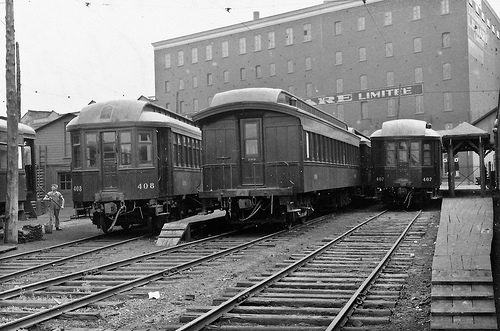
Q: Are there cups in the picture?
A: No, there are no cups.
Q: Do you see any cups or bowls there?
A: No, there are no cups or bowls.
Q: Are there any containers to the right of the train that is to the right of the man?
A: Yes, there is a container to the right of the train.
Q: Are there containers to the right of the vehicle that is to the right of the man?
A: Yes, there is a container to the right of the train.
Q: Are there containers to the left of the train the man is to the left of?
A: No, the container is to the right of the train.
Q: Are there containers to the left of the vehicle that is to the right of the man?
A: No, the container is to the right of the train.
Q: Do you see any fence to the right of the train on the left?
A: No, there is a container to the right of the train.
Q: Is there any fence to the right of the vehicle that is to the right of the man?
A: No, there is a container to the right of the train.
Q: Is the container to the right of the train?
A: Yes, the container is to the right of the train.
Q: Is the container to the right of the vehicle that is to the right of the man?
A: Yes, the container is to the right of the train.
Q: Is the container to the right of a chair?
A: No, the container is to the right of the train.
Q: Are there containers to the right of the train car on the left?
A: Yes, there is a container to the right of the train car.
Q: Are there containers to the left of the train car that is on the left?
A: No, the container is to the right of the train car.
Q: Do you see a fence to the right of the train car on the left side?
A: No, there is a container to the right of the train car.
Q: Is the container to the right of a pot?
A: No, the container is to the right of a train car.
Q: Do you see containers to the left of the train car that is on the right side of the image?
A: Yes, there is a container to the left of the train car.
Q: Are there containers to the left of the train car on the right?
A: Yes, there is a container to the left of the train car.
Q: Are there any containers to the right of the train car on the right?
A: No, the container is to the left of the train car.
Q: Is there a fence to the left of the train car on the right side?
A: No, there is a container to the left of the train car.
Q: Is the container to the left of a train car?
A: Yes, the container is to the left of a train car.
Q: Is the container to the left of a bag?
A: No, the container is to the left of a train car.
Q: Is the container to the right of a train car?
A: No, the container is to the left of a train car.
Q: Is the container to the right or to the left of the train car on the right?
A: The container is to the left of the train car.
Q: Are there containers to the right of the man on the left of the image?
A: Yes, there is a container to the right of the man.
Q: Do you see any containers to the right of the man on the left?
A: Yes, there is a container to the right of the man.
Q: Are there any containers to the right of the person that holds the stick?
A: Yes, there is a container to the right of the man.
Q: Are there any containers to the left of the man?
A: No, the container is to the right of the man.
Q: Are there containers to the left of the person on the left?
A: No, the container is to the right of the man.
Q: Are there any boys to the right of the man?
A: No, there is a container to the right of the man.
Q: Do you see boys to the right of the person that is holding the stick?
A: No, there is a container to the right of the man.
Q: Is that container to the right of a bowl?
A: No, the container is to the right of a man.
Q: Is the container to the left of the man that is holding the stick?
A: No, the container is to the right of the man.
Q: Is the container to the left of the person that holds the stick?
A: No, the container is to the right of the man.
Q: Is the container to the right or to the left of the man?
A: The container is to the right of the man.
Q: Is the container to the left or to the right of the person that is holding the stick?
A: The container is to the right of the man.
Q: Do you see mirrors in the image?
A: No, there are no mirrors.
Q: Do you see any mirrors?
A: No, there are no mirrors.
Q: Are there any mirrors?
A: No, there are no mirrors.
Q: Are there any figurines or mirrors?
A: No, there are no mirrors or figurines.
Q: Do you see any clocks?
A: No, there are no clocks.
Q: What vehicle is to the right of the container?
A: The vehicle is a train car.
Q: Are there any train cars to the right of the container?
A: Yes, there is a train car to the right of the container.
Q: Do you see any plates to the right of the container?
A: No, there is a train car to the right of the container.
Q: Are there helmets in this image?
A: No, there are no helmets.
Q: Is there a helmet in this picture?
A: No, there are no helmets.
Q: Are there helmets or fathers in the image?
A: No, there are no helmets or fathers.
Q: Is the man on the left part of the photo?
A: Yes, the man is on the left of the image.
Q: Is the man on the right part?
A: No, the man is on the left of the image.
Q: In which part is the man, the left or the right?
A: The man is on the left of the image.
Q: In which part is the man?
A: The man is on the left of the image.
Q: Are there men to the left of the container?
A: Yes, there is a man to the left of the container.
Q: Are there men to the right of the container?
A: No, the man is to the left of the container.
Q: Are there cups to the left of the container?
A: No, there is a man to the left of the container.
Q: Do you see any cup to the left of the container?
A: No, there is a man to the left of the container.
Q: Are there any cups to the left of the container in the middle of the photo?
A: No, there is a man to the left of the container.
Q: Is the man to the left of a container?
A: Yes, the man is to the left of a container.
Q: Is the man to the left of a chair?
A: No, the man is to the left of a container.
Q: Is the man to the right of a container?
A: No, the man is to the left of a container.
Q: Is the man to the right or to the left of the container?
A: The man is to the left of the container.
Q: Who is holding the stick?
A: The man is holding the stick.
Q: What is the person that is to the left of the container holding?
A: The man is holding the stick.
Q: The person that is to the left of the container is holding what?
A: The man is holding the stick.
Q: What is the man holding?
A: The man is holding the stick.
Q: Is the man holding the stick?
A: Yes, the man is holding the stick.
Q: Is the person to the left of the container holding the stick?
A: Yes, the man is holding the stick.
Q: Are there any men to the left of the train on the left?
A: Yes, there is a man to the left of the train.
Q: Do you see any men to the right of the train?
A: No, the man is to the left of the train.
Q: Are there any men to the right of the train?
A: No, the man is to the left of the train.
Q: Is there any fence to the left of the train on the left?
A: No, there is a man to the left of the train.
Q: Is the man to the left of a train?
A: Yes, the man is to the left of a train.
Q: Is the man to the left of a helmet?
A: No, the man is to the left of a train.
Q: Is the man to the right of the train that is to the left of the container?
A: No, the man is to the left of the train.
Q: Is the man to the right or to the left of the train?
A: The man is to the left of the train.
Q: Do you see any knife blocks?
A: No, there are no knife blocks.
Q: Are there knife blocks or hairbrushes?
A: No, there are no knife blocks or hairbrushes.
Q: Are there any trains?
A: Yes, there is a train.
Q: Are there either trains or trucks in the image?
A: Yes, there is a train.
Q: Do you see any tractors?
A: No, there are no tractors.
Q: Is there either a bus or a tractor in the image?
A: No, there are no tractors or buses.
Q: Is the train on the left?
A: Yes, the train is on the left of the image.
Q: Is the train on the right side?
A: No, the train is on the left of the image.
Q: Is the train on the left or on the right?
A: The train is on the left of the image.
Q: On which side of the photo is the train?
A: The train is on the left of the image.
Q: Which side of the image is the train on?
A: The train is on the left of the image.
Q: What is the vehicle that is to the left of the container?
A: The vehicle is a train.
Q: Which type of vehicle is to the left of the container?
A: The vehicle is a train.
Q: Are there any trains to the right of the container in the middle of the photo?
A: No, the train is to the left of the container.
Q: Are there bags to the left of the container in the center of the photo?
A: No, there is a train to the left of the container.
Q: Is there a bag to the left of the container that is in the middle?
A: No, there is a train to the left of the container.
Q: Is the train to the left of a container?
A: Yes, the train is to the left of a container.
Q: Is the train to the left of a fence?
A: No, the train is to the left of a container.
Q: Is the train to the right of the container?
A: No, the train is to the left of the container.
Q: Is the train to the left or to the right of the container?
A: The train is to the left of the container.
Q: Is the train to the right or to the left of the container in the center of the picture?
A: The train is to the left of the container.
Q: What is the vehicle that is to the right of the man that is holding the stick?
A: The vehicle is a train.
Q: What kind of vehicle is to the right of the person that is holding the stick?
A: The vehicle is a train.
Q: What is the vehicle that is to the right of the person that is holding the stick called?
A: The vehicle is a train.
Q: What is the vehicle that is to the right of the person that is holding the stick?
A: The vehicle is a train.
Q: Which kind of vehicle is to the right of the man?
A: The vehicle is a train.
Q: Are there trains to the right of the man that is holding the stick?
A: Yes, there is a train to the right of the man.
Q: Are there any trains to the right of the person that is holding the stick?
A: Yes, there is a train to the right of the man.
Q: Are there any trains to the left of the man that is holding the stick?
A: No, the train is to the right of the man.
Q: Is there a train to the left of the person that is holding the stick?
A: No, the train is to the right of the man.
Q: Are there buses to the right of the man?
A: No, there is a train to the right of the man.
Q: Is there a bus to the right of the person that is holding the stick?
A: No, there is a train to the right of the man.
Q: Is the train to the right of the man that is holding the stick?
A: Yes, the train is to the right of the man.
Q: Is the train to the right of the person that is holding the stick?
A: Yes, the train is to the right of the man.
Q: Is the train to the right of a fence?
A: No, the train is to the right of the man.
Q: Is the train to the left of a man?
A: No, the train is to the right of a man.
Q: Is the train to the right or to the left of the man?
A: The train is to the right of the man.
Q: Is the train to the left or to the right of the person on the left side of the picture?
A: The train is to the right of the man.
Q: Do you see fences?
A: No, there are no fences.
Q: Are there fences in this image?
A: No, there are no fences.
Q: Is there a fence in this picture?
A: No, there are no fences.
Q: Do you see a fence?
A: No, there are no fences.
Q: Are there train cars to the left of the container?
A: Yes, there is a train car to the left of the container.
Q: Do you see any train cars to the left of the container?
A: Yes, there is a train car to the left of the container.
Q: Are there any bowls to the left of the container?
A: No, there is a train car to the left of the container.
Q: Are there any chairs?
A: No, there are no chairs.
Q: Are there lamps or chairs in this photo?
A: No, there are no chairs or lamps.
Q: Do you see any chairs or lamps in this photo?
A: No, there are no chairs or lamps.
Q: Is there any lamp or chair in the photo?
A: No, there are no chairs or lamps.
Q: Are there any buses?
A: No, there are no buses.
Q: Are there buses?
A: No, there are no buses.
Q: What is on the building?
A: The sign is on the building.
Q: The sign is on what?
A: The sign is on the building.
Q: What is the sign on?
A: The sign is on the building.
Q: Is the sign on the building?
A: Yes, the sign is on the building.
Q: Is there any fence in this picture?
A: No, there are no fences.